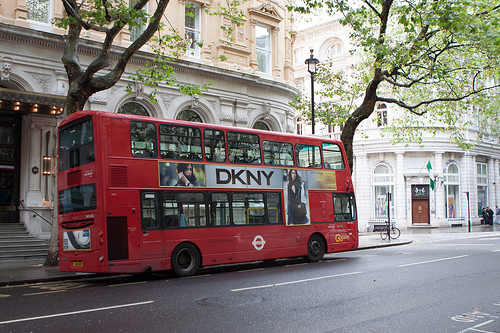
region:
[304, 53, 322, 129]
a black lamp post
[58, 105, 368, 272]
a red bus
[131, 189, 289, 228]
a window on the bus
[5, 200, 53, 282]
stairs in front of the building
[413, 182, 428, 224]
a door on the building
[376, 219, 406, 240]
a bike on the street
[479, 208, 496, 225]
people standing on the street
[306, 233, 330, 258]
the tire of the bus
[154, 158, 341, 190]
an advertisement on the bus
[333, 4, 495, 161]
a tree next to the street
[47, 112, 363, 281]
a red double-decked bus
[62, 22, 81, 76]
a limb of a tree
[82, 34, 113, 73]
a limb of a tree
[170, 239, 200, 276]
the wheel of a bus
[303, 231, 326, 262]
the wheel of a bus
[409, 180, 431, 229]
a door to a building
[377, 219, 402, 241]
a bicycle leaning a road sign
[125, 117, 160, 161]
a window on a bus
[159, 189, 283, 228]
the windows on a bus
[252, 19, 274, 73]
a window in a building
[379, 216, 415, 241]
a bicycle against a pole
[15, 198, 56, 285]
steps going into the building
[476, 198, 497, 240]
people standing along the street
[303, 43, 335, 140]
a street lamp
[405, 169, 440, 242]
a wooden door going into the business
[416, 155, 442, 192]
a green and white flag above the door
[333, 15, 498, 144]
a tree hanging over the street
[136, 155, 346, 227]
advertisement on side of the bus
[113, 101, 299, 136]
arches over the windows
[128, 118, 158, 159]
glass window on bus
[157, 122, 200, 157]
glass window on bus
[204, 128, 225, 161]
glass window on bus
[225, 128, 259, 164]
glass window on bus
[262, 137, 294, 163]
glass window on bus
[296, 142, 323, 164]
glass window on bus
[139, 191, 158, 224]
glass window on bus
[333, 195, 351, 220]
glass window on bus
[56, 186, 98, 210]
glass window on bus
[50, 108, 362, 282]
A red double decker bus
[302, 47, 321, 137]
A tall street lamp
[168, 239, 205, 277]
A round black tire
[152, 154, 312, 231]
A clothing advertisement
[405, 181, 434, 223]
A brown wooden door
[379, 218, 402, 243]
A black pedal bike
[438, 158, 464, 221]
A rounded glass window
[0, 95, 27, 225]
A tall brown door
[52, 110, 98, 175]
A window on the back of the bus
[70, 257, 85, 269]
A small yellow license plate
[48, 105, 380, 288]
bus on the road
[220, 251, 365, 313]
line on the road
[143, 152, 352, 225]
sign on the bus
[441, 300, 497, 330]
writing on the road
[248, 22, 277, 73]
window on the building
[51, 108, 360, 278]
the bus is of the double decker type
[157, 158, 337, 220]
a sign is besides the bus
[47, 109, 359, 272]
the bus is painted red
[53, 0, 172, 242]
a tree is behind the bus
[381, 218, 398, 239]
a bicycle is chained to a pole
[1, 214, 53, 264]
steps run up to the entrence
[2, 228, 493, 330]
markings are in the street